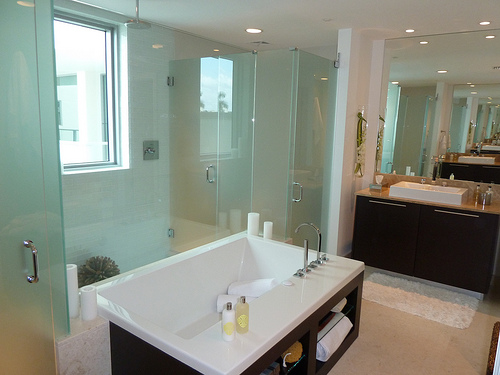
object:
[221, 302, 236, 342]
bottle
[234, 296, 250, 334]
bottle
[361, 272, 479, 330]
rug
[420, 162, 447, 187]
faucet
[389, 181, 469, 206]
sink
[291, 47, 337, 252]
door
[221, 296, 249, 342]
bottle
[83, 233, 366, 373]
bathtub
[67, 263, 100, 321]
towel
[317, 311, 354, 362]
paper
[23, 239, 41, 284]
handle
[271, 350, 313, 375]
shelf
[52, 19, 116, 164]
window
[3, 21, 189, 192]
wall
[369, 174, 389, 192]
candle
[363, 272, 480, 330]
mat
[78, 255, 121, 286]
ball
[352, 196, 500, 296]
drawer